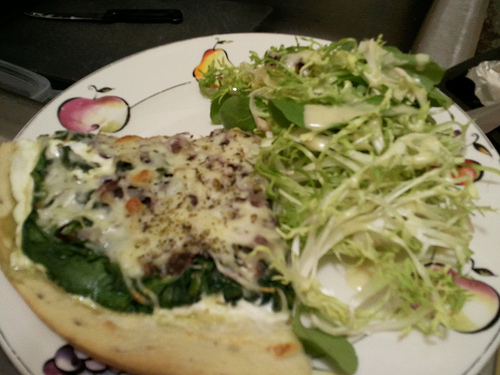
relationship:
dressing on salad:
[290, 113, 345, 156] [186, 33, 498, 373]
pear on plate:
[194, 40, 231, 80] [3, 32, 499, 373]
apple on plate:
[52, 94, 133, 124] [42, 47, 448, 336]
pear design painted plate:
[192, 38, 236, 80] [3, 32, 499, 373]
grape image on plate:
[45, 344, 94, 370] [3, 32, 499, 373]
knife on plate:
[22, 9, 183, 25] [55, 14, 239, 151]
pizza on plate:
[1, 120, 308, 372] [3, 32, 499, 373]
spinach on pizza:
[19, 129, 297, 316] [1, 120, 308, 372]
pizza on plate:
[0, 126, 311, 375] [3, 32, 499, 373]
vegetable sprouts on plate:
[265, 68, 478, 339] [3, 32, 499, 373]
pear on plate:
[193, 36, 237, 88] [75, 44, 152, 92]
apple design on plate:
[53, 86, 138, 136] [3, 32, 499, 373]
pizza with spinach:
[0, 126, 311, 375] [100, 176, 230, 284]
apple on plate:
[57, 84, 130, 133] [3, 32, 499, 373]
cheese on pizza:
[13, 129, 292, 324] [1, 120, 308, 372]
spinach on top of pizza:
[24, 225, 135, 318] [1, 120, 308, 372]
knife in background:
[21, 3, 188, 34] [2, 1, 458, 39]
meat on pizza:
[168, 137, 193, 162] [1, 120, 308, 372]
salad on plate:
[0, 34, 500, 375] [3, 32, 499, 373]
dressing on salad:
[251, 32, 498, 343] [214, 36, 472, 318]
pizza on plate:
[0, 126, 311, 375] [42, 81, 495, 293]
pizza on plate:
[1, 120, 308, 372] [113, 74, 496, 296]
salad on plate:
[18, 26, 487, 373] [0, 31, 500, 375]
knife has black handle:
[22, 9, 183, 25] [109, 3, 192, 29]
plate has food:
[28, 69, 468, 369] [182, 34, 476, 327]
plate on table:
[28, 69, 468, 369] [4, 66, 74, 146]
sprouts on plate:
[200, 41, 492, 373] [3, 32, 499, 373]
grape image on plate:
[42, 344, 123, 375] [3, 32, 499, 373]